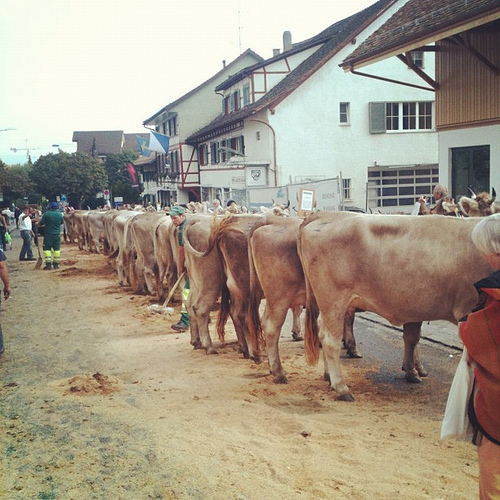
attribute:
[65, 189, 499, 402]
cows — brown, standing in a row, standing in line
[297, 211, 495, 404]
cow — brown, large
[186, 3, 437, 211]
home — white, wide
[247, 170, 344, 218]
structure — large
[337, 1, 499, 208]
building — close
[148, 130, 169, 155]
flag — blue, white, diagonal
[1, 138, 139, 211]
trees — green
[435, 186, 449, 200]
hair — gray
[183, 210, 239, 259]
tail — swishing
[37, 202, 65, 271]
person — wearing green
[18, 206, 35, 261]
man — pointing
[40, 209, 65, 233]
shirt — green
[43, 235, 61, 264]
pants — green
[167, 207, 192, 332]
man — cleaning up, in green, wearing green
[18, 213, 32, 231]
shirt — white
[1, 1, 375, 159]
sky — white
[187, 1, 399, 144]
rooftop — black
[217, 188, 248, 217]
fence — chain link